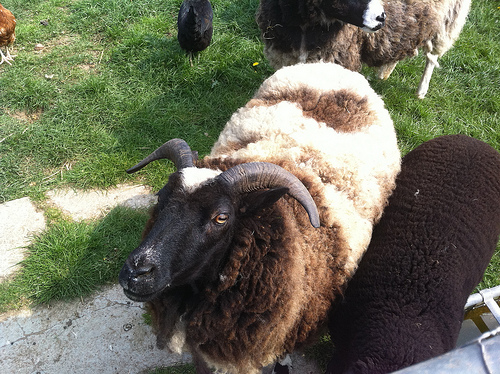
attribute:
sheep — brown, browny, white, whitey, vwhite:
[111, 47, 380, 351]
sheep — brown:
[389, 153, 491, 324]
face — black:
[127, 174, 230, 307]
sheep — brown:
[355, 1, 465, 88]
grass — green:
[51, 35, 92, 64]